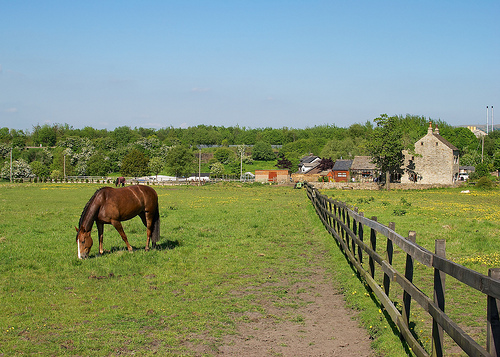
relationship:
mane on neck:
[75, 185, 100, 227] [77, 187, 97, 232]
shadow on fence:
[405, 251, 412, 315] [299, 180, 500, 357]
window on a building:
[336, 170, 348, 177] [327, 153, 352, 183]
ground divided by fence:
[0, 186, 500, 357] [299, 180, 499, 356]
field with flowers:
[19, 155, 408, 325] [246, 187, 266, 204]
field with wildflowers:
[19, 155, 408, 325] [39, 183, 85, 192]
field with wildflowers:
[19, 155, 408, 325] [459, 250, 499, 267]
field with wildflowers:
[19, 155, 408, 325] [213, 198, 239, 204]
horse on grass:
[73, 183, 165, 262] [0, 181, 402, 354]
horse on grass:
[73, 183, 165, 262] [2, 177, 497, 354]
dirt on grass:
[186, 240, 377, 355] [0, 181, 402, 354]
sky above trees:
[0, 0, 500, 132] [0, 126, 75, 181]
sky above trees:
[0, 0, 500, 132] [80, 126, 159, 176]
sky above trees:
[0, 0, 500, 132] [207, 124, 327, 175]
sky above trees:
[0, 0, 500, 132] [346, 113, 459, 155]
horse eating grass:
[73, 183, 165, 262] [1, 181, 347, 354]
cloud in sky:
[0, 0, 500, 133] [0, 0, 500, 132]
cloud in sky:
[341, 32, 433, 88] [0, 0, 500, 132]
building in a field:
[330, 157, 354, 183] [1, 178, 497, 355]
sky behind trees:
[53, 26, 478, 100] [74, 125, 325, 160]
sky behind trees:
[53, 26, 478, 100] [0, 125, 83, 185]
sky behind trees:
[53, 26, 478, 100] [243, 125, 356, 180]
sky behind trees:
[53, 26, 478, 100] [349, 113, 412, 184]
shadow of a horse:
[154, 238, 180, 251] [74, 180, 159, 257]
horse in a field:
[74, 180, 159, 257] [0, 183, 404, 355]